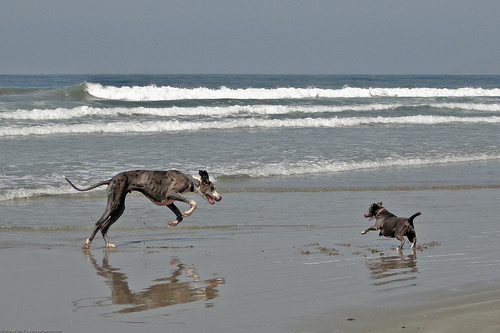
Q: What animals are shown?
A: Dogs.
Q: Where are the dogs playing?
A: The beach.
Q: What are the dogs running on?
A: Sand.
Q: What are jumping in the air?
A: Two dogs.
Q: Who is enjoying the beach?
A: The dogs.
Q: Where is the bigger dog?
A: On the left.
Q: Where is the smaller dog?
A: On the right.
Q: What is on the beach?
A: Two dogs.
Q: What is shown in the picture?
A: The large body of water.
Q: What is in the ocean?
A: The small waves.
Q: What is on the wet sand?
A: The large dog.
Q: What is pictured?
A: The reflection of the dogs on the sand.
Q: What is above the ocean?
A: The sky.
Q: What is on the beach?
A: Two dogs.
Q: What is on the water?
A: Waves.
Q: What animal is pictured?
A: Dogs.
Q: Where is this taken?
A: The beach.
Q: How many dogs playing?
A: Two.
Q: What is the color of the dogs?
A: Gray and black.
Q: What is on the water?
A: Dogs.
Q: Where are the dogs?
A: On the shore.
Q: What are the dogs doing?
A: Playing.